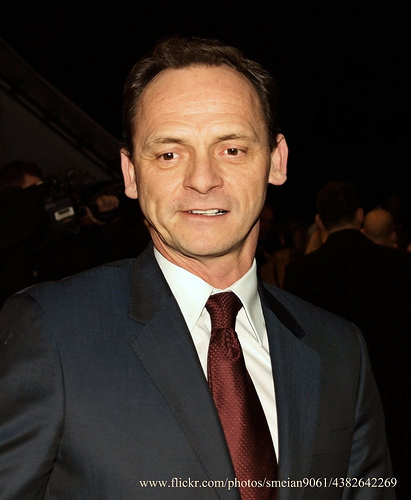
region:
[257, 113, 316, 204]
Flesh colored human ear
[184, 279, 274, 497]
Red tie around neck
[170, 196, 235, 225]
Open mouth showing teeth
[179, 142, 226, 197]
Human nose on face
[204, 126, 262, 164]
Human eye with eyebrow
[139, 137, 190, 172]
Human eye with eyebrow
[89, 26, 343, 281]
Human head with brown hair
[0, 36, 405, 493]
Person with suit and red tie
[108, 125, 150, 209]
Human ear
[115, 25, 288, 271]
Human head with hair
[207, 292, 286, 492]
it is a red tie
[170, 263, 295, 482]
it is a white shirt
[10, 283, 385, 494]
the suit is grey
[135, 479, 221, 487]
it is written flickr.com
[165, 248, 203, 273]
neck has wrinkles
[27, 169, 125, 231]
camera behind man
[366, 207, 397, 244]
man with bald head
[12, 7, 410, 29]
sky is very dark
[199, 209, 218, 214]
mans teeth are white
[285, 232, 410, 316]
man with black coat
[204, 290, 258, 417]
the tie is brown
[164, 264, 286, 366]
the shirt is white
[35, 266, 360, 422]
the coat is black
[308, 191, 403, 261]
the people are standing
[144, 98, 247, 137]
the man is old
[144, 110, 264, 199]
wrinkles around the eyes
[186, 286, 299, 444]
tie is on the neck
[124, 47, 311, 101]
the hair is brown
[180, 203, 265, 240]
the mouth is partially open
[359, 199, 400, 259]
the head is bald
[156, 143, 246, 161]
two dark brown eyes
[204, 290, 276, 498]
maroon silk necktie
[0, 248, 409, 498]
formal black suit and shirt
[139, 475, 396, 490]
flickr photo identification number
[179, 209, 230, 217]
mouth open exposing teeth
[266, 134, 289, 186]
man's left ear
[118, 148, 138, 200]
man's right ear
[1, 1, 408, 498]
man at crowded formal event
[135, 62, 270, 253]
face with wrinkles and receding hairline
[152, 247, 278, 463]
plain white collared dress shirt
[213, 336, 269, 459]
tie is maroon color.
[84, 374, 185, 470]
coat is black in color.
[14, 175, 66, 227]
camera is black in color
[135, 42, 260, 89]
hair is blonde.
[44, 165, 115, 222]
man is holding the camera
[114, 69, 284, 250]
man is looking front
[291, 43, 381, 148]
sky is black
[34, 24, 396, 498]
picture is taken during night time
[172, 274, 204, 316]
shirt color is white.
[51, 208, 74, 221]
label is white in color.